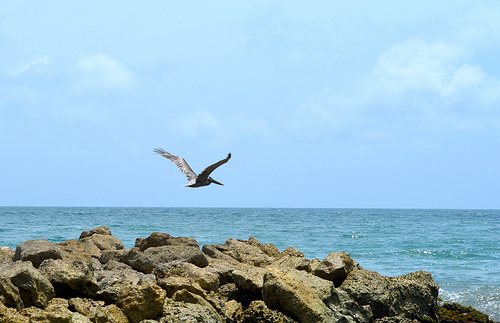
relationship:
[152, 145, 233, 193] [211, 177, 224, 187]
pelican has beak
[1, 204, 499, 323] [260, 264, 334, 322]
ocean behind rocks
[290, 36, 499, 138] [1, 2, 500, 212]
clouds are in sky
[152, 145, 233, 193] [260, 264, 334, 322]
pelican flying over rocks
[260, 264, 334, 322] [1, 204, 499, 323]
rocks are near ocean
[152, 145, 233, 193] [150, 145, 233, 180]
pelican has wingspan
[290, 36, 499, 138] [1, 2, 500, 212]
clouds formed in sky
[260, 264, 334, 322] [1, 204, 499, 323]
rocks at edge of ocean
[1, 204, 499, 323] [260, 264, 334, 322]
ocean hits rocks